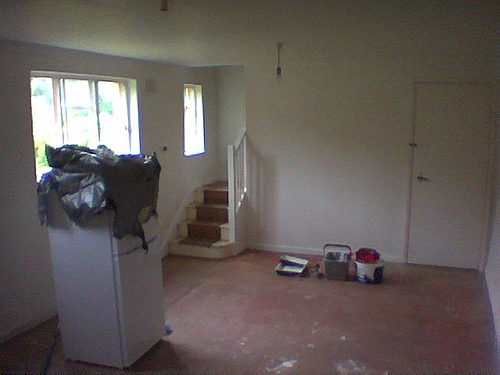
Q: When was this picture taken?
A: During the day.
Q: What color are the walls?
A: White.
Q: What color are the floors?
A: Brown.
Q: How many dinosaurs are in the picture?
A: Zero.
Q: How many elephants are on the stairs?
A: Zero.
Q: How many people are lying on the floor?
A: Zero.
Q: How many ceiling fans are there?
A: Zero.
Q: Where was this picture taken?
A: At a house.